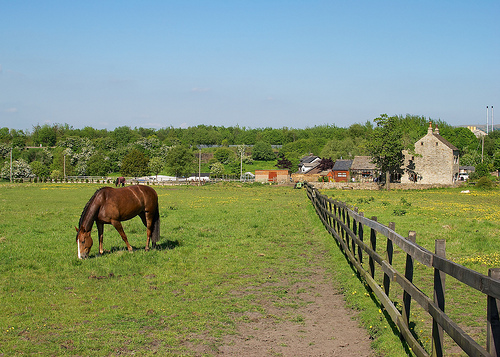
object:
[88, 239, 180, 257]
shadow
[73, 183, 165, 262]
horse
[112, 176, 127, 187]
horse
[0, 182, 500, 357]
grass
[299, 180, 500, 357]
fence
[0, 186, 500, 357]
ground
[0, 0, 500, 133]
cloud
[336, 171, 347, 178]
window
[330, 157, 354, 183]
building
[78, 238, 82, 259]
stripe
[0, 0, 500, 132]
sky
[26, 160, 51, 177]
trees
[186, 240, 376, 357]
dirt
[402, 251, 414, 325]
shadow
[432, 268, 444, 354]
shadow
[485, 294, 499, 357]
shadow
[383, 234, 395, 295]
shadow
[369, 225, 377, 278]
shadow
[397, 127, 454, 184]
wall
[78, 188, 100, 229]
mane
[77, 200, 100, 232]
neck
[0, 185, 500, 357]
field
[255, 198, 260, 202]
flowers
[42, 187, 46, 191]
wildflowers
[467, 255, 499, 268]
wildflowers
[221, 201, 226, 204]
wildflowers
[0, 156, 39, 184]
trees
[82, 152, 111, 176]
trees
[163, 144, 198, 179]
trees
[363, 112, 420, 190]
trees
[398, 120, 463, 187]
barn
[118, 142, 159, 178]
trees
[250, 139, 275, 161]
trees